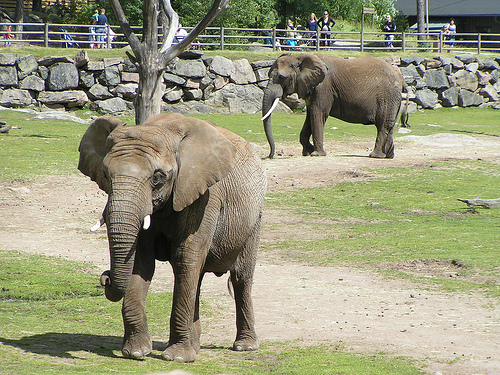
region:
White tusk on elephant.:
[270, 100, 284, 122]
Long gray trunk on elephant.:
[243, 84, 304, 185]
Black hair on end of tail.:
[392, 103, 413, 139]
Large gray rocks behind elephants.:
[411, 62, 470, 111]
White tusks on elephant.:
[70, 207, 164, 233]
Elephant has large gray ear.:
[178, 113, 223, 209]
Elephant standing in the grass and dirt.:
[93, 291, 222, 373]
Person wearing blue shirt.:
[303, 15, 318, 31]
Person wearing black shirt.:
[320, 15, 330, 32]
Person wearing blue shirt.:
[94, 12, 114, 26]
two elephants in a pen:
[71, 28, 413, 372]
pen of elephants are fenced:
[1, 15, 499, 365]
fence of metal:
[0, 17, 498, 52]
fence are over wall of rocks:
[5, 18, 262, 109]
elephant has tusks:
[70, 99, 278, 374]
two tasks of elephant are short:
[80, 210, 156, 236]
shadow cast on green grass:
[5, 306, 115, 368]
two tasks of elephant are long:
[250, 92, 287, 124]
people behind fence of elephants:
[6, 7, 481, 52]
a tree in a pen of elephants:
[88, 0, 223, 118]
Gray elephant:
[74, 111, 265, 362]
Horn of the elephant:
[97, 169, 149, 303]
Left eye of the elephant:
[151, 165, 169, 186]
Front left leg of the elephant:
[164, 236, 214, 363]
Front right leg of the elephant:
[114, 235, 156, 362]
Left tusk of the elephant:
[141, 206, 153, 233]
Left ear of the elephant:
[171, 103, 238, 214]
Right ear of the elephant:
[75, 118, 116, 199]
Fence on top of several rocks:
[1, 19, 496, 113]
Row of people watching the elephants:
[0, 9, 462, 53]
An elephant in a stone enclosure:
[260, 53, 410, 160]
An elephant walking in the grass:
[77, 111, 267, 362]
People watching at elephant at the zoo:
[262, 10, 455, 158]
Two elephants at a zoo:
[46, 54, 409, 363]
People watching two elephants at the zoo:
[78, 8, 410, 361]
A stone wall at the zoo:
[1, 51, 134, 112]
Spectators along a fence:
[282, 6, 397, 46]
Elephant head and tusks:
[260, 54, 328, 158]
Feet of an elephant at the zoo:
[122, 319, 194, 364]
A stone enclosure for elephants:
[1, 54, 498, 110]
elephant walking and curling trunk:
[64, 108, 272, 367]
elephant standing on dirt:
[253, 41, 416, 164]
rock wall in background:
[3, 52, 120, 106]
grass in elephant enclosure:
[10, 267, 82, 342]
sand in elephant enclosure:
[283, 289, 461, 331]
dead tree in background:
[95, 0, 239, 122]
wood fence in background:
[211, 24, 278, 47]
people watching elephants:
[254, 7, 407, 48]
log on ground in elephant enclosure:
[451, 186, 499, 225]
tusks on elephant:
[255, 86, 283, 126]